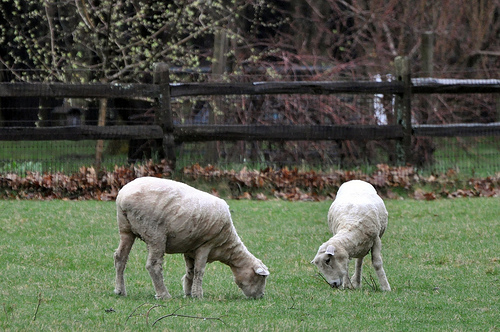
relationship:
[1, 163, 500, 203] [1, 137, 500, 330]
leaves are laying on grass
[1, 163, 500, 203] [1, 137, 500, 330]
leaves are on grass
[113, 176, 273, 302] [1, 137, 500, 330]
sheep standing on grass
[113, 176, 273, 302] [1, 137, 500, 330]
sheep are standing on grass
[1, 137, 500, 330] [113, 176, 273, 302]
grass under sheep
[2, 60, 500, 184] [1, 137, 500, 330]
fence in grass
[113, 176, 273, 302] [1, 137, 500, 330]
sheep eating grass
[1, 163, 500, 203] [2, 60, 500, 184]
leaves along fence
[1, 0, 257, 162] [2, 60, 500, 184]
tree behind fence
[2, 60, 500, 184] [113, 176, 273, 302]
fence behind sheep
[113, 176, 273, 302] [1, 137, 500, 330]
sheep are eating grass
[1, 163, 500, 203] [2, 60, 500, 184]
leaves are up against fence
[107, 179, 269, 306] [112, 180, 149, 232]
sheep has a rear end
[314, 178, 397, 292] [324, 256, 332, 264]
sheep has an eye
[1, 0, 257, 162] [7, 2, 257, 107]
tree with leaves